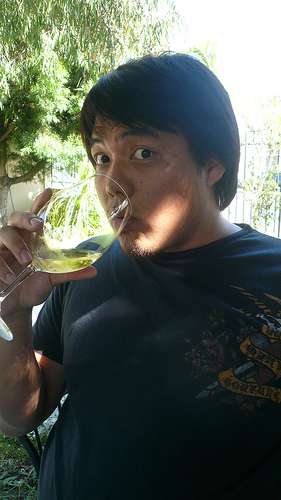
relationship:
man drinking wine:
[0, 52, 281, 499] [0, 173, 135, 343]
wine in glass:
[0, 173, 135, 343] [0, 172, 136, 342]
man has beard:
[0, 52, 281, 499] [119, 234, 157, 259]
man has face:
[0, 52, 281, 499] [83, 111, 208, 262]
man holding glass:
[0, 52, 281, 499] [0, 172, 136, 342]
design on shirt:
[181, 282, 280, 414] [30, 224, 280, 499]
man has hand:
[0, 52, 281, 499] [0, 187, 102, 319]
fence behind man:
[220, 129, 278, 242] [0, 52, 281, 499]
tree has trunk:
[0, 1, 184, 237] [0, 138, 12, 220]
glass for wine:
[0, 172, 136, 342] [0, 173, 135, 343]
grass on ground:
[12, 470, 15, 482] [0, 238, 281, 499]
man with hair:
[0, 52, 281, 499] [78, 50, 240, 210]